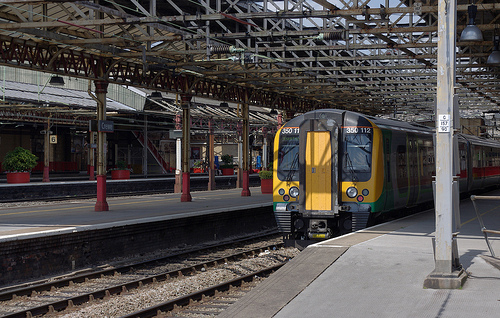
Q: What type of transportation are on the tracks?
A: Train.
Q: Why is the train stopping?
A: For passengers.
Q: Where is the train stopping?
A: Station.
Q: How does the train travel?
A: On the tracks.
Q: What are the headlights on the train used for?
A: Night vision.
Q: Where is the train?
A: On the tracks.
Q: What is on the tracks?
A: The train.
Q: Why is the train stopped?
A: To let passengers on and off.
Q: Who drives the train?
A: A conductor.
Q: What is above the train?
A: Steel beams.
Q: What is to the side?
A: A building.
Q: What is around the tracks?
A: Gravel.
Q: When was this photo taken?
A: Daytime.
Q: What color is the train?
A: Yellow.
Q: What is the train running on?
A: Tracks.